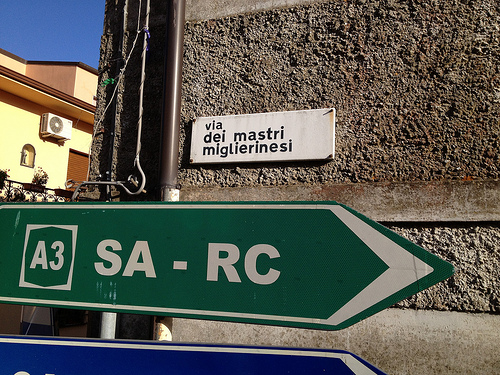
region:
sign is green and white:
[2, 185, 424, 349]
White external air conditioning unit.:
[36, 103, 106, 153]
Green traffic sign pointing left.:
[6, 188, 461, 337]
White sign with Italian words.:
[188, 97, 346, 168]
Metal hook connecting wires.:
[95, 5, 159, 197]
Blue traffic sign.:
[1, 326, 383, 373]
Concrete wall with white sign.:
[172, 8, 499, 313]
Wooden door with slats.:
[54, 137, 99, 202]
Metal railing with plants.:
[1, 172, 90, 223]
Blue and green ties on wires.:
[95, 19, 178, 94]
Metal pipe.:
[153, 2, 198, 205]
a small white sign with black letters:
[186, 102, 346, 167]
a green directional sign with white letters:
[1, 200, 430, 322]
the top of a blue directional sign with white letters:
[6, 318, 390, 370]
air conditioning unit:
[28, 92, 95, 147]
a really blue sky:
[13, 3, 110, 83]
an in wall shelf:
[13, 137, 55, 174]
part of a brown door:
[58, 143, 120, 200]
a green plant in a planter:
[21, 160, 66, 199]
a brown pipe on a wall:
[161, 10, 208, 180]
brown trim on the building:
[18, 75, 95, 122]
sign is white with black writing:
[183, 105, 348, 180]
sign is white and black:
[172, 101, 356, 183]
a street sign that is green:
[24, 166, 385, 358]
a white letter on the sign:
[202, 230, 236, 287]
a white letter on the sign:
[30, 235, 50, 282]